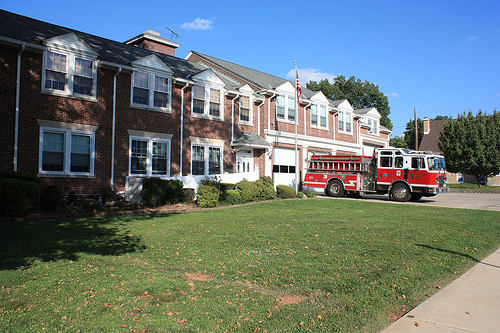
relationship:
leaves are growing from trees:
[444, 110, 499, 180] [411, 111, 483, 184]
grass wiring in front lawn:
[183, 214, 473, 266] [1, 192, 456, 316]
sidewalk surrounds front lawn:
[418, 287, 483, 322] [1, 192, 456, 316]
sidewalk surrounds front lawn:
[379, 180, 500, 331] [1, 192, 456, 316]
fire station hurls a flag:
[0, 5, 397, 219] [291, 60, 303, 109]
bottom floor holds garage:
[8, 142, 442, 197] [268, 145, 303, 195]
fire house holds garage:
[2, 0, 394, 195] [307, 145, 327, 168]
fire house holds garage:
[2, 0, 394, 195] [334, 146, 363, 159]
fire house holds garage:
[2, 0, 394, 195] [363, 139, 392, 160]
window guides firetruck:
[287, 164, 296, 173] [303, 147, 453, 199]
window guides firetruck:
[278, 164, 288, 174] [303, 147, 453, 199]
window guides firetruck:
[270, 163, 280, 171] [303, 147, 453, 199]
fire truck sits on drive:
[302, 148, 446, 200] [308, 188, 484, 208]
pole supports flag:
[269, 61, 350, 202] [286, 56, 309, 106]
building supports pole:
[46, 26, 491, 237] [269, 61, 350, 202]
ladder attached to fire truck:
[309, 146, 381, 183] [305, 153, 450, 195]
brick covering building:
[33, 97, 65, 120] [5, 14, 425, 205]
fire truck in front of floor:
[302, 150, 462, 200] [366, 133, 429, 160]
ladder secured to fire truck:
[308, 159, 367, 171] [300, 148, 453, 200]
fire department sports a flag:
[9, 2, 462, 284] [289, 60, 305, 102]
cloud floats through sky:
[180, 16, 218, 36] [172, 8, 445, 68]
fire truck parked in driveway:
[302, 148, 446, 200] [315, 192, 499, 217]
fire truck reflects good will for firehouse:
[302, 148, 446, 200] [2, 10, 405, 197]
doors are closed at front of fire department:
[224, 145, 271, 182] [6, 10, 434, 303]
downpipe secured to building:
[110, 68, 117, 188] [7, 77, 384, 204]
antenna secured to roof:
[160, 26, 185, 53] [5, 37, 391, 83]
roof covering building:
[5, 37, 391, 83] [7, 97, 425, 222]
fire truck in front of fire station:
[302, 148, 446, 200] [0, 3, 394, 222]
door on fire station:
[271, 147, 300, 193] [3, 9, 388, 206]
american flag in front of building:
[294, 60, 303, 106] [3, 11, 416, 220]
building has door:
[0, 6, 391, 212] [234, 149, 256, 189]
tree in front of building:
[443, 116, 498, 176] [3, 11, 416, 220]